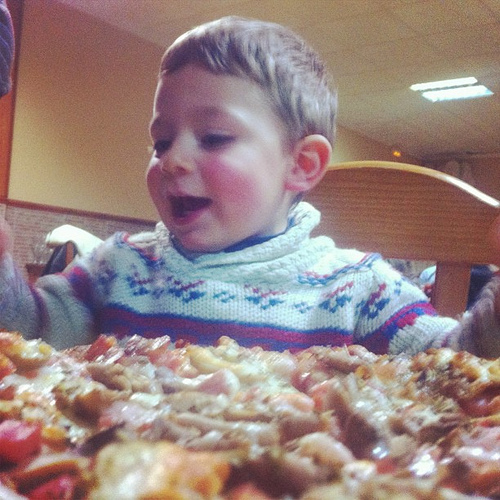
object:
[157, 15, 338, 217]
hair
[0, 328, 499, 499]
pizza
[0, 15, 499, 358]
boy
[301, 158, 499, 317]
chair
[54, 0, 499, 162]
ceiling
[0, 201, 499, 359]
sweater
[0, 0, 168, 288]
wall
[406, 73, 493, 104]
light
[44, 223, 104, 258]
cloth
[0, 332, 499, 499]
toppings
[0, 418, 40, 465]
tomatoes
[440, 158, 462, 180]
sign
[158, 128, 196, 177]
nose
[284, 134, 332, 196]
ear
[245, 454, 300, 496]
sausage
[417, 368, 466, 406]
peppers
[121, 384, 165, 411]
cheese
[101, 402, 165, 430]
onions